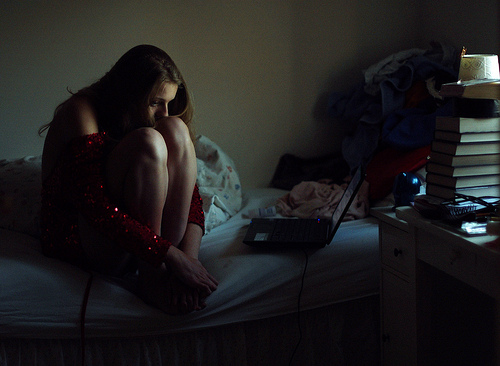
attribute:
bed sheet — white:
[204, 181, 265, 268]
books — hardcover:
[346, 161, 498, 301]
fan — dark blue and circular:
[386, 128, 498, 257]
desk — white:
[206, 208, 444, 326]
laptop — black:
[244, 161, 364, 253]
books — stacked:
[420, 112, 499, 203]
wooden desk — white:
[368, 202, 499, 364]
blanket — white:
[0, 132, 246, 240]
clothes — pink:
[276, 172, 369, 223]